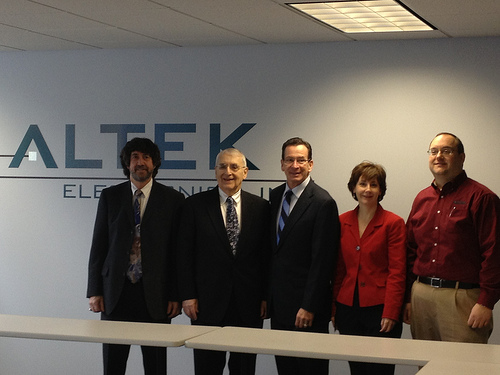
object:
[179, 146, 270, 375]
man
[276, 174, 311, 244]
shirt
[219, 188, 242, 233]
shirt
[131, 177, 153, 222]
shirt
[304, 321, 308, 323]
ring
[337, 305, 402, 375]
pants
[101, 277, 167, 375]
pants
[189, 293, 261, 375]
pants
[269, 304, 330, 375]
pants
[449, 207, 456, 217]
pen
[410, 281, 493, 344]
pants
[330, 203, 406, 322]
jacket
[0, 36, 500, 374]
wall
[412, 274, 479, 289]
belt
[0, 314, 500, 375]
white table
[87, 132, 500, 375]
people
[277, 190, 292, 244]
tie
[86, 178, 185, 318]
jacket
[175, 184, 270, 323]
jacket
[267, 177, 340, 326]
jacket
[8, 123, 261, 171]
letters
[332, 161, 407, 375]
lady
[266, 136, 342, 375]
man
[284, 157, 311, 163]
glasses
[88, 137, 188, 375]
man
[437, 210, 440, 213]
button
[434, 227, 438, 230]
button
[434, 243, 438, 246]
button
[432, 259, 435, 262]
button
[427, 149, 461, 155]
glasses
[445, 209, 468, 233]
pocket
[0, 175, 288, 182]
line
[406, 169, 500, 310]
shirt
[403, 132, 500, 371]
man